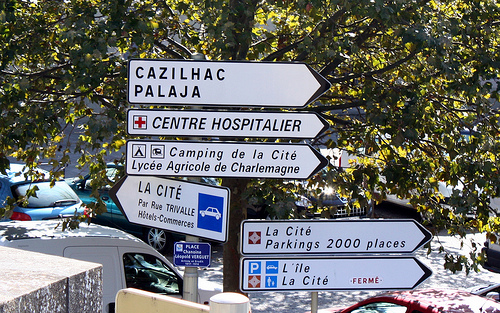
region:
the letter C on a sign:
[131, 63, 146, 80]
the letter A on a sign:
[146, 63, 156, 80]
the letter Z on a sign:
[155, 64, 170, 81]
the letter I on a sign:
[168, 65, 177, 81]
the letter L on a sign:
[178, 64, 188, 81]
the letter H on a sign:
[188, 65, 203, 82]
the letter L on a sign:
[153, 81, 167, 99]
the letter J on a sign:
[178, 82, 190, 101]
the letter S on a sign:
[232, 117, 242, 129]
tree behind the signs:
[370, 48, 465, 170]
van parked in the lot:
[13, 208, 174, 292]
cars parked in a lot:
[5, 159, 116, 221]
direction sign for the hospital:
[125, 112, 330, 140]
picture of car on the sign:
[196, 187, 225, 236]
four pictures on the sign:
[245, 260, 281, 294]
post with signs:
[308, 290, 321, 311]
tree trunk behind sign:
[221, 236, 236, 289]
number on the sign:
[325, 237, 365, 255]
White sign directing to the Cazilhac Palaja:
[123, 54, 325, 113]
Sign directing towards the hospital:
[122, 104, 332, 144]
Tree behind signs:
[27, 2, 494, 248]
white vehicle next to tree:
[2, 208, 212, 310]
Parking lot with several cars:
[2, 54, 452, 306]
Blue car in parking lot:
[2, 164, 94, 227]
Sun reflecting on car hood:
[305, 174, 338, 196]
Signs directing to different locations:
[106, 40, 425, 298]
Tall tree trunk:
[212, 7, 255, 312]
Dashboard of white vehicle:
[123, 251, 180, 306]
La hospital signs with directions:
[112, 73, 290, 257]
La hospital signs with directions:
[118, 87, 369, 239]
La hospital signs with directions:
[106, 39, 343, 224]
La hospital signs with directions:
[181, 85, 391, 194]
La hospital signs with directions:
[168, 59, 408, 248]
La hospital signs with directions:
[94, 71, 383, 227]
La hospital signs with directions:
[26, 14, 372, 226]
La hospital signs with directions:
[103, 71, 426, 94]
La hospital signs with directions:
[23, 14, 338, 261]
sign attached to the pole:
[129, 62, 327, 107]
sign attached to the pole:
[130, 107, 332, 142]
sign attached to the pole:
[126, 140, 321, 184]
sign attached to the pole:
[238, 221, 433, 252]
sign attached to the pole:
[237, 258, 431, 289]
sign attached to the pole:
[114, 178, 234, 239]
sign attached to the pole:
[171, 240, 218, 276]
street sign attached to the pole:
[126, 59, 333, 106]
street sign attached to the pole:
[128, 106, 330, 143]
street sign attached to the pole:
[126, 139, 326, 181]